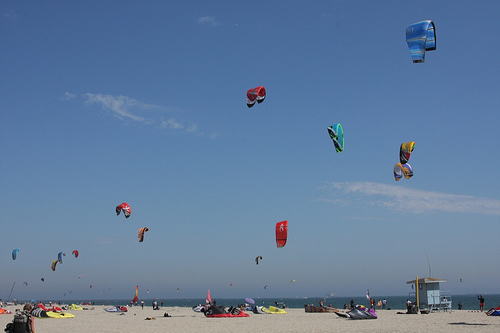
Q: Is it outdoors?
A: Yes, it is outdoors.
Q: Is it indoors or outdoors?
A: It is outdoors.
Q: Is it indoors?
A: No, it is outdoors.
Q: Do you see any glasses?
A: No, there are no glasses.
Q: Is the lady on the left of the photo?
A: Yes, the lady is on the left of the image.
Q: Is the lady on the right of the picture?
A: No, the lady is on the left of the image.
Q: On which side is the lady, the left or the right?
A: The lady is on the left of the image.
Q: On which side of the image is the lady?
A: The lady is on the left of the image.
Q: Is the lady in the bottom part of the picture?
A: Yes, the lady is in the bottom of the image.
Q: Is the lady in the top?
A: No, the lady is in the bottom of the image.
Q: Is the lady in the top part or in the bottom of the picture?
A: The lady is in the bottom of the image.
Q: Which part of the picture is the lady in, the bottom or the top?
A: The lady is in the bottom of the image.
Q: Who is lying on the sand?
A: The lady is lying on the sand.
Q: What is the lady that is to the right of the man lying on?
A: The lady is lying on the sand.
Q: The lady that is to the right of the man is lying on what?
A: The lady is lying on the sand.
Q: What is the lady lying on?
A: The lady is lying on the sand.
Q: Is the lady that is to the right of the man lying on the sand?
A: Yes, the lady is lying on the sand.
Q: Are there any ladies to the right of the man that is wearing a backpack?
A: Yes, there is a lady to the right of the man.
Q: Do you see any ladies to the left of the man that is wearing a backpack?
A: No, the lady is to the right of the man.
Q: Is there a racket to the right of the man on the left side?
A: No, there is a lady to the right of the man.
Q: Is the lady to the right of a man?
A: Yes, the lady is to the right of a man.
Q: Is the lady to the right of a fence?
A: No, the lady is to the right of a man.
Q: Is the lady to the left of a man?
A: No, the lady is to the right of a man.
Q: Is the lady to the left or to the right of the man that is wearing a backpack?
A: The lady is to the right of the man.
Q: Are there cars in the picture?
A: No, there are no cars.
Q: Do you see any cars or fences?
A: No, there are no cars or fences.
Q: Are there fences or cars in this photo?
A: No, there are no cars or fences.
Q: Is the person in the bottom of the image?
A: Yes, the person is in the bottom of the image.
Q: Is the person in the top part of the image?
A: No, the person is in the bottom of the image.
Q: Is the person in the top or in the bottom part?
A: The person is in the bottom of the image.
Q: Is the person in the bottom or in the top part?
A: The person is in the bottom of the image.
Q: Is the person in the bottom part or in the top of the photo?
A: The person is in the bottom of the image.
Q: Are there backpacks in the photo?
A: Yes, there is a backpack.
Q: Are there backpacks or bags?
A: Yes, there is a backpack.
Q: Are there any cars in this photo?
A: No, there are no cars.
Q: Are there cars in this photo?
A: No, there are no cars.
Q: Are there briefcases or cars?
A: No, there are no cars or briefcases.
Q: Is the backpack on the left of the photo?
A: Yes, the backpack is on the left of the image.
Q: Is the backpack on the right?
A: No, the backpack is on the left of the image.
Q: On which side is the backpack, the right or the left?
A: The backpack is on the left of the image.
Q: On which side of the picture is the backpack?
A: The backpack is on the left of the image.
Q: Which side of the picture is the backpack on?
A: The backpack is on the left of the image.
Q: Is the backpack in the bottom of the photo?
A: Yes, the backpack is in the bottom of the image.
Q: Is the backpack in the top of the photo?
A: No, the backpack is in the bottom of the image.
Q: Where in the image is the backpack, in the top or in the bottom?
A: The backpack is in the bottom of the image.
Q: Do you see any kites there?
A: Yes, there is a kite.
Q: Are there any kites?
A: Yes, there is a kite.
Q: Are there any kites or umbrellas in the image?
A: Yes, there is a kite.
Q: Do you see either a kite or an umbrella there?
A: Yes, there is a kite.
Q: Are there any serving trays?
A: No, there are no serving trays.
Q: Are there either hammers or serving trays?
A: No, there are no serving trays or hammers.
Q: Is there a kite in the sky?
A: Yes, there is a kite in the sky.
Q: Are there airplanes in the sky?
A: No, there is a kite in the sky.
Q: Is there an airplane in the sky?
A: No, there is a kite in the sky.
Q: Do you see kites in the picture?
A: Yes, there is a kite.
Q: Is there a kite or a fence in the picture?
A: Yes, there is a kite.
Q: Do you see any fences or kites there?
A: Yes, there is a kite.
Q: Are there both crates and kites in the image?
A: No, there is a kite but no crates.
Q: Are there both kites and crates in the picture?
A: No, there is a kite but no crates.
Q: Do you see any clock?
A: No, there are no clocks.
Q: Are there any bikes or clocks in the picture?
A: No, there are no clocks or bikes.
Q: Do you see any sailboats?
A: No, there are no sailboats.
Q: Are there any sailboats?
A: No, there are no sailboats.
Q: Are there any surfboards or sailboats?
A: No, there are no sailboats or surfboards.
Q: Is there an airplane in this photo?
A: No, there are no airplanes.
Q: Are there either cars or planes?
A: No, there are no planes or cars.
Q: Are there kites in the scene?
A: Yes, there is a kite.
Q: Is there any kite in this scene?
A: Yes, there is a kite.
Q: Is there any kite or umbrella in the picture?
A: Yes, there is a kite.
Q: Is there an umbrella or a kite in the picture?
A: Yes, there is a kite.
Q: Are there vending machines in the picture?
A: No, there are no vending machines.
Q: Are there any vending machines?
A: No, there are no vending machines.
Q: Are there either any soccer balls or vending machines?
A: No, there are no vending machines or soccer balls.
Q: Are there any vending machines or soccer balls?
A: No, there are no vending machines or soccer balls.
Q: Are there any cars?
A: No, there are no cars.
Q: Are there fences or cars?
A: No, there are no cars or fences.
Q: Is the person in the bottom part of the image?
A: Yes, the person is in the bottom of the image.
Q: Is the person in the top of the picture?
A: No, the person is in the bottom of the image.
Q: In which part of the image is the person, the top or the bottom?
A: The person is in the bottom of the image.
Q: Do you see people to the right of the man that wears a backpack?
A: Yes, there is a person to the right of the man.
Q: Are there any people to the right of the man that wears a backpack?
A: Yes, there is a person to the right of the man.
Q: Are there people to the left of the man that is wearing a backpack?
A: No, the person is to the right of the man.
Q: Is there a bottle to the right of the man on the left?
A: No, there is a person to the right of the man.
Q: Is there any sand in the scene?
A: Yes, there is sand.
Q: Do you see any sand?
A: Yes, there is sand.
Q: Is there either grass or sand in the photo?
A: Yes, there is sand.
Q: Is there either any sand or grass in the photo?
A: Yes, there is sand.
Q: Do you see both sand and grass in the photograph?
A: No, there is sand but no grass.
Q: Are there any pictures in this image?
A: No, there are no pictures.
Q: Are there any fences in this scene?
A: No, there are no fences.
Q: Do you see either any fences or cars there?
A: No, there are no fences or cars.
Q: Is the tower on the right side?
A: Yes, the tower is on the right of the image.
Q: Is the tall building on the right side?
A: Yes, the tower is on the right of the image.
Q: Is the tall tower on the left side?
A: No, the tower is on the right of the image.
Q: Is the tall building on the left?
A: No, the tower is on the right of the image.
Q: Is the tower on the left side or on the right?
A: The tower is on the right of the image.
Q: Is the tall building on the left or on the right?
A: The tower is on the right of the image.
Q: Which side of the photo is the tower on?
A: The tower is on the right of the image.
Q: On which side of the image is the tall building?
A: The tower is on the right of the image.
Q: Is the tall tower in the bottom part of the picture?
A: Yes, the tower is in the bottom of the image.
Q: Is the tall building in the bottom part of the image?
A: Yes, the tower is in the bottom of the image.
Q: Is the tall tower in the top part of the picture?
A: No, the tower is in the bottom of the image.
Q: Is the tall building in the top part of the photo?
A: No, the tower is in the bottom of the image.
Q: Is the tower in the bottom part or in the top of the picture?
A: The tower is in the bottom of the image.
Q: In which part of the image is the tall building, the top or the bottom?
A: The tower is in the bottom of the image.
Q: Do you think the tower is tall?
A: Yes, the tower is tall.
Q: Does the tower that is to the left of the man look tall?
A: Yes, the tower is tall.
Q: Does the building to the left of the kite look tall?
A: Yes, the tower is tall.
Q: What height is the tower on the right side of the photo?
A: The tower is tall.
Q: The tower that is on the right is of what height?
A: The tower is tall.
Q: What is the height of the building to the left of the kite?
A: The tower is tall.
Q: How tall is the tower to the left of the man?
A: The tower is tall.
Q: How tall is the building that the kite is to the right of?
A: The tower is tall.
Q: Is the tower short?
A: No, the tower is tall.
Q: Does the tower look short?
A: No, the tower is tall.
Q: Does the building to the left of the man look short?
A: No, the tower is tall.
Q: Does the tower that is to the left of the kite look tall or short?
A: The tower is tall.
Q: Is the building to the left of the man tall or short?
A: The tower is tall.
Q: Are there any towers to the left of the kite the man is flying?
A: Yes, there is a tower to the left of the kite.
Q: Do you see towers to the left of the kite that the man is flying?
A: Yes, there is a tower to the left of the kite.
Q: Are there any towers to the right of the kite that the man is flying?
A: No, the tower is to the left of the kite.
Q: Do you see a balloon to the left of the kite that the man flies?
A: No, there is a tower to the left of the kite.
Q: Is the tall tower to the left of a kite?
A: Yes, the tower is to the left of a kite.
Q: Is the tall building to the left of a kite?
A: Yes, the tower is to the left of a kite.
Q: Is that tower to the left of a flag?
A: No, the tower is to the left of a kite.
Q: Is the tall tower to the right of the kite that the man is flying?
A: No, the tower is to the left of the kite.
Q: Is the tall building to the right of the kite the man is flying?
A: No, the tower is to the left of the kite.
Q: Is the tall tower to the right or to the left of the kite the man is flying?
A: The tower is to the left of the kite.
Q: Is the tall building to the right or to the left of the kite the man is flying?
A: The tower is to the left of the kite.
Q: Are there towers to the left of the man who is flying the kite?
A: Yes, there is a tower to the left of the man.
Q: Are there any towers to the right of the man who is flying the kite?
A: No, the tower is to the left of the man.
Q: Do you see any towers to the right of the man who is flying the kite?
A: No, the tower is to the left of the man.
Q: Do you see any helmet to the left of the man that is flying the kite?
A: No, there is a tower to the left of the man.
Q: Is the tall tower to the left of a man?
A: Yes, the tower is to the left of a man.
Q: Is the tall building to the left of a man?
A: Yes, the tower is to the left of a man.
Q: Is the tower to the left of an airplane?
A: No, the tower is to the left of a man.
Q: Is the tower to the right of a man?
A: No, the tower is to the left of a man.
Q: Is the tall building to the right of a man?
A: No, the tower is to the left of a man.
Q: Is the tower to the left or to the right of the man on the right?
A: The tower is to the left of the man.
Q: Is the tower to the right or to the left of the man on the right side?
A: The tower is to the left of the man.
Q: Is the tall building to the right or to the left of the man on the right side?
A: The tower is to the left of the man.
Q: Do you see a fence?
A: No, there are no fences.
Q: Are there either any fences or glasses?
A: No, there are no fences or glasses.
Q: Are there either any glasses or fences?
A: No, there are no fences or glasses.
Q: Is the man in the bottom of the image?
A: Yes, the man is in the bottom of the image.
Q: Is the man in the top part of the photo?
A: No, the man is in the bottom of the image.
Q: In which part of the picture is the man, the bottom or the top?
A: The man is in the bottom of the image.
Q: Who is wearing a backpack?
A: The man is wearing a backpack.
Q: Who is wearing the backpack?
A: The man is wearing a backpack.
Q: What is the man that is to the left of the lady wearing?
A: The man is wearing a backpack.